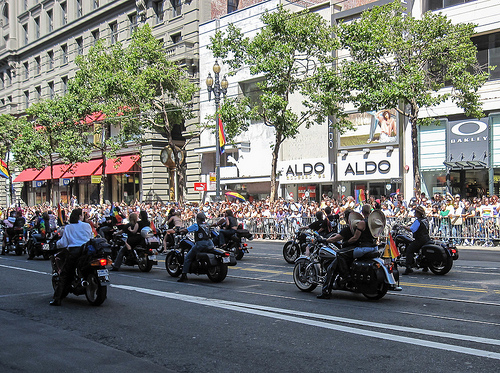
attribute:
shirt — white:
[63, 223, 89, 248]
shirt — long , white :
[52, 223, 97, 245]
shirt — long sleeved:
[54, 222, 96, 253]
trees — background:
[1, 3, 486, 207]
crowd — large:
[0, 193, 496, 245]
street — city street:
[0, 155, 498, 208]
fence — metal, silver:
[242, 215, 498, 240]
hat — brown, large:
[368, 209, 385, 237]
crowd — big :
[1, 190, 498, 250]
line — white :
[0, 262, 218, 307]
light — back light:
[209, 245, 236, 267]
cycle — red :
[54, 247, 109, 309]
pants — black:
[45, 246, 92, 295]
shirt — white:
[42, 216, 93, 251]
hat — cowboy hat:
[341, 206, 372, 237]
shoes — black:
[43, 288, 68, 313]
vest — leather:
[185, 221, 239, 251]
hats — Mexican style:
[346, 208, 389, 240]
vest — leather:
[410, 212, 435, 239]